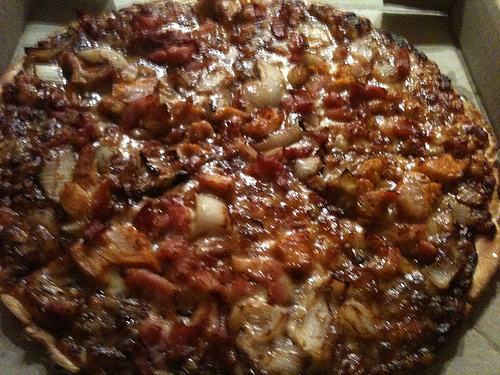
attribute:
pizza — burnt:
[24, 27, 419, 369]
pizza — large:
[281, 32, 472, 236]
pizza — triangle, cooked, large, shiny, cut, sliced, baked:
[5, 6, 491, 371]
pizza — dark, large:
[59, 43, 417, 371]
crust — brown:
[20, 9, 479, 326]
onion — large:
[77, 122, 140, 171]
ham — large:
[110, 73, 166, 123]